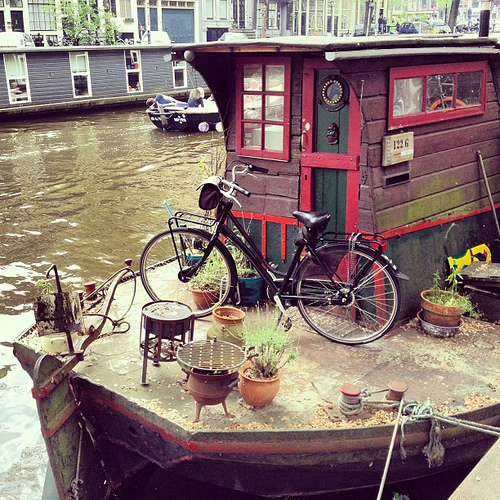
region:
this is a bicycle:
[191, 178, 406, 347]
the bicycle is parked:
[188, 208, 331, 290]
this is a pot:
[246, 373, 278, 414]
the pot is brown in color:
[251, 373, 277, 403]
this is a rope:
[375, 410, 397, 498]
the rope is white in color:
[377, 428, 400, 490]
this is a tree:
[56, 6, 111, 33]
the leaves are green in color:
[76, 2, 98, 28]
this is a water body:
[29, 144, 121, 217]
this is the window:
[246, 67, 291, 130]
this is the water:
[56, 117, 98, 164]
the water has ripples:
[59, 141, 144, 199]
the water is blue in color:
[66, 130, 104, 150]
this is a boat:
[142, 85, 219, 127]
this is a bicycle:
[121, 161, 400, 343]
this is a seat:
[296, 210, 333, 229]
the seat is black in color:
[298, 210, 316, 219]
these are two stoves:
[146, 321, 244, 413]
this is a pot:
[249, 383, 275, 405]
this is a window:
[233, 67, 288, 150]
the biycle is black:
[152, 165, 407, 362]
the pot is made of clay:
[227, 367, 295, 408]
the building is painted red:
[304, 150, 374, 227]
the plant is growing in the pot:
[239, 339, 302, 403]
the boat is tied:
[335, 387, 487, 472]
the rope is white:
[344, 398, 499, 446]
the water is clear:
[1, 116, 228, 268]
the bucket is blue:
[241, 273, 272, 315]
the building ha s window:
[230, 90, 302, 164]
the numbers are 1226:
[380, 136, 438, 168]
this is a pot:
[238, 371, 297, 411]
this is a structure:
[273, 70, 455, 272]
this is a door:
[307, 107, 352, 214]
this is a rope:
[371, 405, 403, 498]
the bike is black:
[125, 142, 427, 352]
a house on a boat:
[150, 13, 482, 417]